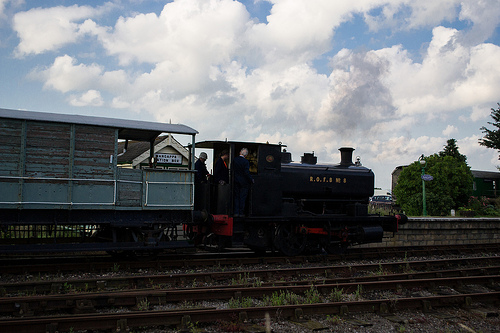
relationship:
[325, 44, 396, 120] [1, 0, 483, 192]
cloud hanging in sky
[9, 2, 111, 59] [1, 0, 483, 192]
cloud hanging in sky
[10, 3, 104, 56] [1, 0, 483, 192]
cloud hanging in sky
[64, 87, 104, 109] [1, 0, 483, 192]
cloud hanging in sky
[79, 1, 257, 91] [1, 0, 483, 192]
cloud hanging in sky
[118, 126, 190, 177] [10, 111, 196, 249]
window in train car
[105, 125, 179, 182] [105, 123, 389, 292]
building by train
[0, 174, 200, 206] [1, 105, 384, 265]
railing on a train